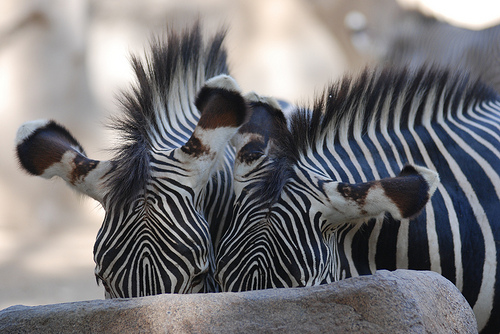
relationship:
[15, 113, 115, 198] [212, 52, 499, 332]
ear on zebra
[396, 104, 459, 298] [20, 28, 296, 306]
stripe on zebra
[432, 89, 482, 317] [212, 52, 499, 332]
stripe on zebra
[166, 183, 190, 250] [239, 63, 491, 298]
stripe on zebra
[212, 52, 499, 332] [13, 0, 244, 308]
zebra eating with zebra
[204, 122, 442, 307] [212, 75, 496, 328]
head on a zebra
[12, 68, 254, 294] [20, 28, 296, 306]
head on a zebra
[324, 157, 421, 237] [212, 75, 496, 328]
ear on a zebra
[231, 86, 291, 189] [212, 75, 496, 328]
ear on a zebra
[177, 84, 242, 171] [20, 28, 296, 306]
ear on a zebra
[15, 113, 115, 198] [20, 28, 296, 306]
ear on a zebra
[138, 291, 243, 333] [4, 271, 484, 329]
light on a rock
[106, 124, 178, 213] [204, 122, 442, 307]
zebra's hair on a head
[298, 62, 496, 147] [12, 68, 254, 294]
zebra's hair on a head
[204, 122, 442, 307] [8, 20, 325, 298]
head on a zebra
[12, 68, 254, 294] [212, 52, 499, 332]
head on a zebra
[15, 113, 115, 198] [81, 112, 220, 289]
ear on a zebra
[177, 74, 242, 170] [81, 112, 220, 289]
ear on a zebra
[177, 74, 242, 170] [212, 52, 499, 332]
ear on a zebra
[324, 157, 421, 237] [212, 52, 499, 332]
ear on a zebra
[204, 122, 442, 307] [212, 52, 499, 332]
head on a zebra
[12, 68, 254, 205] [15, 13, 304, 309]
head on a zebra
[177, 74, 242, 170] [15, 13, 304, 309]
ear on a zebra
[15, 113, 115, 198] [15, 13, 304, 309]
ear on a zebra